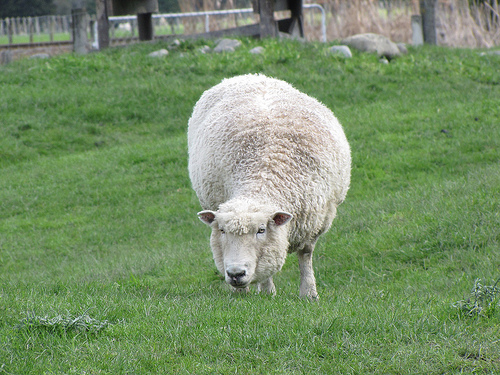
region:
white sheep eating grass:
[173, 73, 352, 311]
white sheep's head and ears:
[186, 192, 304, 290]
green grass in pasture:
[40, 278, 467, 353]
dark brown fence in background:
[15, 11, 325, 61]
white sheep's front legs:
[228, 233, 356, 314]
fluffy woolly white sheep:
[185, 83, 335, 300]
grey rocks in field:
[126, 29, 407, 69]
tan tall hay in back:
[324, 6, 485, 46]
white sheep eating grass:
[54, 18, 465, 335]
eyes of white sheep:
[212, 220, 275, 236]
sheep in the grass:
[157, 68, 409, 315]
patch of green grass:
[200, 300, 240, 317]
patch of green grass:
[102, 307, 131, 335]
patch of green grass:
[371, 270, 391, 292]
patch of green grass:
[412, 148, 439, 170]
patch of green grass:
[71, 314, 101, 340]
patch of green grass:
[105, 155, 119, 180]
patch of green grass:
[446, 334, 483, 359]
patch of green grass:
[416, 267, 435, 288]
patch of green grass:
[112, 220, 137, 244]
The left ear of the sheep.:
[192, 203, 217, 225]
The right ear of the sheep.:
[271, 205, 296, 223]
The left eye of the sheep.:
[209, 222, 234, 242]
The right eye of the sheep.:
[254, 222, 274, 239]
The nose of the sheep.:
[220, 264, 252, 277]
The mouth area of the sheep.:
[222, 275, 249, 289]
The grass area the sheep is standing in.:
[19, 66, 472, 343]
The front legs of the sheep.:
[252, 251, 319, 305]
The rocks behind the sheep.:
[20, 32, 433, 77]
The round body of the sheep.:
[191, 63, 338, 230]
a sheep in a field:
[184, 74, 350, 303]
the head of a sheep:
[194, 195, 296, 297]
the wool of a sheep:
[224, 95, 301, 145]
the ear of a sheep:
[270, 206, 292, 230]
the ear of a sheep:
[191, 206, 221, 226]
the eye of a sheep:
[253, 222, 273, 242]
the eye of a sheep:
[211, 222, 232, 240]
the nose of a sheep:
[224, 265, 245, 282]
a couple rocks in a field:
[324, 20, 409, 74]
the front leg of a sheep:
[296, 235, 322, 309]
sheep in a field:
[165, 63, 362, 308]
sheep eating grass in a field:
[164, 67, 357, 311]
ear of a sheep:
[270, 207, 295, 227]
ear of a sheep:
[192, 208, 212, 223]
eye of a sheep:
[255, 222, 265, 235]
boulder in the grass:
[340, 25, 406, 58]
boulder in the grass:
[315, 35, 356, 61]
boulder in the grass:
[241, 40, 267, 56]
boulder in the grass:
[210, 33, 246, 53]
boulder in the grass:
[145, 43, 171, 62]